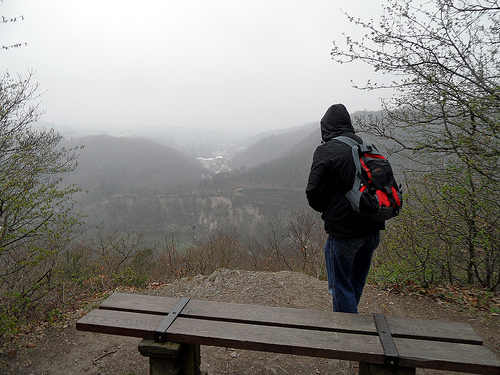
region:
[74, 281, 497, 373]
a wooden park bench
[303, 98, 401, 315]
a person standing on ledge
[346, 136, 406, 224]
a red and black backpack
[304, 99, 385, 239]
a black hoodie jacket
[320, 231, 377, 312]
a pair of blue jeans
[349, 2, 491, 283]
a group of trees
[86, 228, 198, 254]
a body of water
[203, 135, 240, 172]
a town in distance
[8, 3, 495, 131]
a white hazy sky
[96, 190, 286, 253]
a large hillside with trees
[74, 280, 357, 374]
The bench is wooden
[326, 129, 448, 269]
The person has a backpack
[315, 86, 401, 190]
The person has their hood up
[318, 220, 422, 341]
The person has jeans on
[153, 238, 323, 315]
The cliff has rocks on it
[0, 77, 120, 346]
The tree is bare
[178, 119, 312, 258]
The day looks cloudy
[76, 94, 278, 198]
The mountains are in the distance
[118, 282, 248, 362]
The bench has a metal brace on it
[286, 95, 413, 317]
The person is standing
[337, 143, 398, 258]
red black and gray back pack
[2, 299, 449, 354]
wooden bench with metal straps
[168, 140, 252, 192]
snow in a mountain valley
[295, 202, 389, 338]
a pair of blue jeans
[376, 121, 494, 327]
small green buds on trees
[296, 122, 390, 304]
a person with a back pack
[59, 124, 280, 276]
mountains and a valley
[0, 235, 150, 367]
brown leaves on the ground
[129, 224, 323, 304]
cement edge of a cliff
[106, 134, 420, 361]
person over looking a view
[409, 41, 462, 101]
the branches of a tree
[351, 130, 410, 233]
a black and red backpack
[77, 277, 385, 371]
a wood plank bench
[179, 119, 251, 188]
the valley of a hills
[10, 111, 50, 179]
the branches of a tree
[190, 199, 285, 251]
a bunch of trees in fog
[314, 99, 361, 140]
a head with a hood on it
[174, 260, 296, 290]
the edge of a cliff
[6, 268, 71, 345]
brush on a pathway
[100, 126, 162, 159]
tops of trees on a hill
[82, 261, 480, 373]
wooden bench in photograph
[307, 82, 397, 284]
person wearing black jacket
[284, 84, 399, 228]
person with red backpack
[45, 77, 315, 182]
mountains in photograph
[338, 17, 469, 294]
trees with budding leaves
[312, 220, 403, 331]
person in blue jeans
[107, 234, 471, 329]
person standing on cliff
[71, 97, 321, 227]
sky is foggy in backgroudn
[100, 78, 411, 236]
person standing above valley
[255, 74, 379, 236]
person looking out at mountains